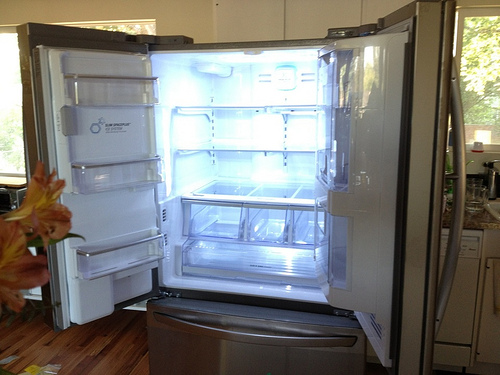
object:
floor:
[1, 308, 145, 374]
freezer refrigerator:
[143, 300, 384, 372]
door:
[15, 21, 165, 331]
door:
[314, 0, 466, 375]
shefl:
[169, 42, 329, 121]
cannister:
[475, 157, 499, 195]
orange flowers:
[4, 155, 78, 322]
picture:
[3, 2, 488, 374]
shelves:
[138, 70, 346, 330]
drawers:
[56, 74, 183, 332]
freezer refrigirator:
[27, 0, 474, 370]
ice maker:
[60, 96, 171, 189]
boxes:
[179, 180, 330, 248]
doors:
[14, 16, 430, 373]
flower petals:
[15, 162, 67, 311]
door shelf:
[58, 69, 162, 111]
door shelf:
[64, 152, 164, 194]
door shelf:
[75, 228, 166, 282]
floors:
[38, 335, 125, 372]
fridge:
[38, 29, 466, 360]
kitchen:
[13, 7, 498, 369]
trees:
[467, 21, 497, 118]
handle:
[429, 52, 470, 341]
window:
[408, 8, 498, 175]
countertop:
[444, 194, 494, 236]